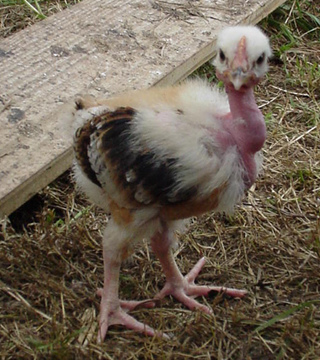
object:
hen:
[79, 21, 279, 336]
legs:
[154, 229, 189, 285]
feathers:
[187, 88, 223, 118]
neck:
[226, 87, 269, 152]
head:
[222, 28, 277, 92]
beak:
[230, 54, 250, 106]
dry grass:
[0, 0, 320, 359]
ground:
[0, 0, 320, 359]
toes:
[171, 287, 223, 313]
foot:
[167, 260, 239, 329]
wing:
[82, 105, 218, 206]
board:
[0, 0, 291, 218]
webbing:
[104, 307, 123, 332]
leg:
[99, 221, 129, 302]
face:
[212, 20, 274, 86]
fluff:
[215, 26, 259, 36]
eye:
[214, 45, 226, 64]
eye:
[254, 38, 271, 69]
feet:
[94, 273, 172, 340]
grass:
[0, 0, 320, 360]